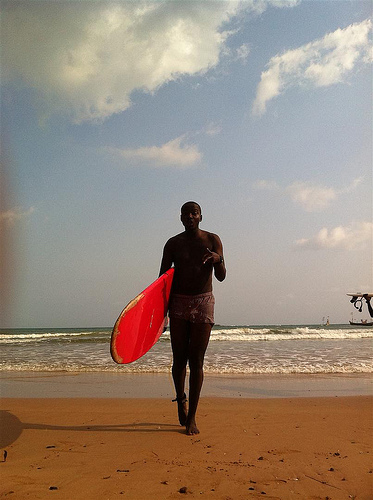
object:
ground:
[1, 377, 371, 496]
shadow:
[0, 408, 182, 454]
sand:
[0, 394, 372, 498]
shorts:
[170, 290, 215, 330]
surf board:
[110, 267, 175, 366]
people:
[320, 315, 330, 327]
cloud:
[1, 22, 371, 253]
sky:
[0, 2, 370, 329]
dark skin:
[156, 199, 227, 435]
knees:
[173, 354, 204, 373]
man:
[158, 198, 226, 435]